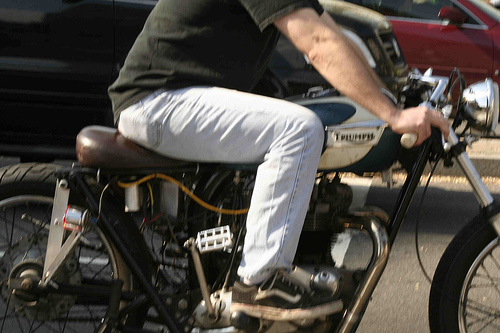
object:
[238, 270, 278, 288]
socks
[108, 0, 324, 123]
shirt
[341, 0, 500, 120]
car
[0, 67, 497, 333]
bike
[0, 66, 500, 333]
motorcycle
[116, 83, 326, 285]
jeans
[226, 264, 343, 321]
shoe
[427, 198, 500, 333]
wheel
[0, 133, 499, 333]
road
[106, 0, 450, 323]
human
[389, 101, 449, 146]
hands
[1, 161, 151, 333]
tire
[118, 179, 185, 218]
motor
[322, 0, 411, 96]
front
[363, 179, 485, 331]
asphalt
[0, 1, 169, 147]
door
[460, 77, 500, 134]
light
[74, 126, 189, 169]
seat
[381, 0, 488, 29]
window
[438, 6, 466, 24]
mirror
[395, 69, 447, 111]
wheel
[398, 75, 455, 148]
handlebar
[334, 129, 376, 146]
print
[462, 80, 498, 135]
headlight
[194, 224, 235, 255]
pedal